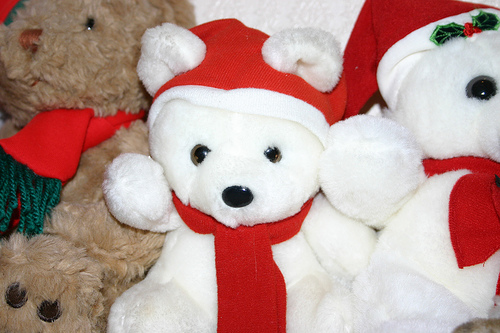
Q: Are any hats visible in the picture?
A: Yes, there is a hat.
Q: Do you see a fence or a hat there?
A: Yes, there is a hat.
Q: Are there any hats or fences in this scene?
A: Yes, there is a hat.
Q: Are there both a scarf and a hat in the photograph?
A: Yes, there are both a hat and a scarf.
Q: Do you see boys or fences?
A: No, there are no fences or boys.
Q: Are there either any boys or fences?
A: No, there are no fences or boys.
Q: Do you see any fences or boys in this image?
A: No, there are no fences or boys.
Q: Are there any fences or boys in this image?
A: No, there are no fences or boys.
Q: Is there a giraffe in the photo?
A: No, there are no giraffes.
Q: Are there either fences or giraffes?
A: No, there are no giraffes or fences.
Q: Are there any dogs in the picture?
A: No, there are no dogs.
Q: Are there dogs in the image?
A: No, there are no dogs.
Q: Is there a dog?
A: No, there are no dogs.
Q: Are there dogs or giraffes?
A: No, there are no dogs or giraffes.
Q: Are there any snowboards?
A: No, there are no snowboards.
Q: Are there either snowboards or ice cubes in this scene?
A: No, there are no snowboards or ice cubes.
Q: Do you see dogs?
A: No, there are no dogs.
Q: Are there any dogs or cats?
A: No, there are no dogs or cats.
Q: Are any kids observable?
A: No, there are no kids.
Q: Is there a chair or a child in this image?
A: No, there are no children or chairs.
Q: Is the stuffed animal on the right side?
A: Yes, the stuffed animal is on the right of the image.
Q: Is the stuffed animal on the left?
A: No, the stuffed animal is on the right of the image.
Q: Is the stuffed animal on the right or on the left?
A: The stuffed animal is on the right of the image.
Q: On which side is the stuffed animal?
A: The stuffed animal is on the right of the image.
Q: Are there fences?
A: No, there are no fences.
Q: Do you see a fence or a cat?
A: No, there are no fences or cats.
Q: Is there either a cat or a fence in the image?
A: No, there are no fences or cats.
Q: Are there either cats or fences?
A: No, there are no fences or cats.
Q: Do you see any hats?
A: Yes, there is a hat.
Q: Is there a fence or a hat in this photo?
A: Yes, there is a hat.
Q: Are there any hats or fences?
A: Yes, there is a hat.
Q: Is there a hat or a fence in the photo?
A: Yes, there is a hat.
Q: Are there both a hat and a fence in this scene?
A: No, there is a hat but no fences.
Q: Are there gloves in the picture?
A: No, there are no gloves.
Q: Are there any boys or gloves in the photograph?
A: No, there are no gloves or boys.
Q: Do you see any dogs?
A: No, there are no dogs.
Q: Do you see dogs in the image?
A: No, there are no dogs.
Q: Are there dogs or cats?
A: No, there are no dogs or cats.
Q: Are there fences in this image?
A: No, there are no fences.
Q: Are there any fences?
A: No, there are no fences.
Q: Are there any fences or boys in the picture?
A: No, there are no fences or boys.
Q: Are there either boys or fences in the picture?
A: No, there are no fences or boys.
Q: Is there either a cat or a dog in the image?
A: No, there are no dogs or cats.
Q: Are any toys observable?
A: Yes, there is a toy.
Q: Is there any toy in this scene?
A: Yes, there is a toy.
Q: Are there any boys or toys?
A: Yes, there is a toy.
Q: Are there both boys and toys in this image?
A: No, there is a toy but no boys.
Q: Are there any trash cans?
A: No, there are no trash cans.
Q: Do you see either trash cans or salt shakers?
A: No, there are no trash cans or salt shakers.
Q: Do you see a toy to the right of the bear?
A: Yes, there is a toy to the right of the bear.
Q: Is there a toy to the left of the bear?
A: No, the toy is to the right of the bear.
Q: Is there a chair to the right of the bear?
A: No, there is a toy to the right of the bear.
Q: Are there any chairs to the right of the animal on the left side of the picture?
A: No, there is a toy to the right of the bear.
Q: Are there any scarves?
A: Yes, there is a scarf.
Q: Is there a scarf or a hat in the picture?
A: Yes, there is a scarf.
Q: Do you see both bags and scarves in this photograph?
A: No, there is a scarf but no bags.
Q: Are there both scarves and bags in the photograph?
A: No, there is a scarf but no bags.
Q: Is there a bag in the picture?
A: No, there are no bags.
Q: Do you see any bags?
A: No, there are no bags.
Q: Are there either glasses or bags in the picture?
A: No, there are no bags or glasses.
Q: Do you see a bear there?
A: Yes, there is a bear.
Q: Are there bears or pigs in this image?
A: Yes, there is a bear.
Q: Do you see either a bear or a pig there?
A: Yes, there is a bear.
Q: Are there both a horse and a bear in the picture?
A: No, there is a bear but no horses.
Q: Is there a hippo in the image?
A: No, there are no hippoes.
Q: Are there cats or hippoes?
A: No, there are no hippoes or cats.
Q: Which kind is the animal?
A: The animal is a bear.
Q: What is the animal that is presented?
A: The animal is a bear.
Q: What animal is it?
A: The animal is a bear.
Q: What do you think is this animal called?
A: This is a bear.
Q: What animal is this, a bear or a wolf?
A: This is a bear.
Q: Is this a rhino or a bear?
A: This is a bear.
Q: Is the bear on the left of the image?
A: Yes, the bear is on the left of the image.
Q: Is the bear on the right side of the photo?
A: No, the bear is on the left of the image.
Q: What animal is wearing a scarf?
A: The bear is wearing a scarf.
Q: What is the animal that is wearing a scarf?
A: The animal is a bear.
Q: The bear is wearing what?
A: The bear is wearing a scarf.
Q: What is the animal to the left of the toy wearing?
A: The bear is wearing a scarf.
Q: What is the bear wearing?
A: The bear is wearing a scarf.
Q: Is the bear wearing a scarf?
A: Yes, the bear is wearing a scarf.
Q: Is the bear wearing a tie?
A: No, the bear is wearing a scarf.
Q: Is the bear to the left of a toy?
A: Yes, the bear is to the left of a toy.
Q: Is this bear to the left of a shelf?
A: No, the bear is to the left of a toy.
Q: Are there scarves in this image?
A: Yes, there is a scarf.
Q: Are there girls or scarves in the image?
A: Yes, there is a scarf.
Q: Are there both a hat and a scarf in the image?
A: Yes, there are both a scarf and a hat.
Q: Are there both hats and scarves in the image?
A: Yes, there are both a scarf and a hat.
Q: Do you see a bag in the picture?
A: No, there are no bags.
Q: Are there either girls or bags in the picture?
A: No, there are no bags or girls.